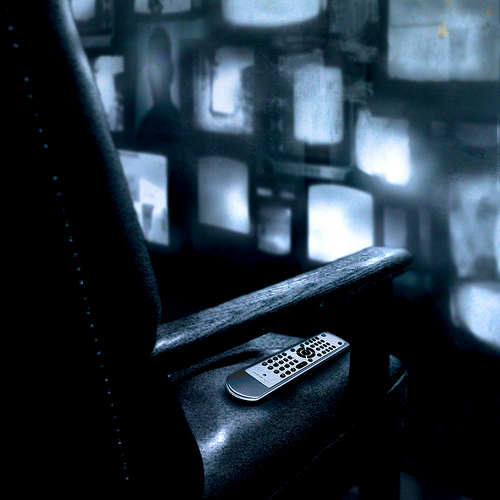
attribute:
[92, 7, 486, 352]
screens — blue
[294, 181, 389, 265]
screen — monitor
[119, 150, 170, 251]
screen — monitor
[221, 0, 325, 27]
screen — background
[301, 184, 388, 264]
screen — monitor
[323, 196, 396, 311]
screen — background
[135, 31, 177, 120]
monitor screen — background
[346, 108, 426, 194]
screen — monitor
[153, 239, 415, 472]
armrest — wood grain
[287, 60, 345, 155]
monitor screen — background